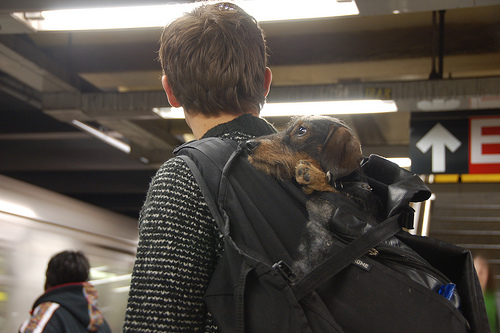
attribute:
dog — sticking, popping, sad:
[259, 119, 308, 167]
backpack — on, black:
[304, 188, 458, 316]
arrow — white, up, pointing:
[411, 132, 474, 188]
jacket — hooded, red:
[34, 277, 75, 332]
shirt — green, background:
[472, 292, 495, 310]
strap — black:
[300, 238, 379, 301]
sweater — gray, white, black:
[138, 176, 198, 302]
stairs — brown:
[430, 189, 499, 281]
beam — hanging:
[68, 80, 144, 120]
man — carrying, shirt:
[121, 45, 348, 331]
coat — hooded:
[38, 286, 110, 333]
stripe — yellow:
[431, 167, 497, 206]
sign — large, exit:
[397, 101, 498, 195]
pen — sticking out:
[425, 268, 458, 314]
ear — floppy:
[319, 109, 354, 175]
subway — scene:
[31, 71, 307, 313]